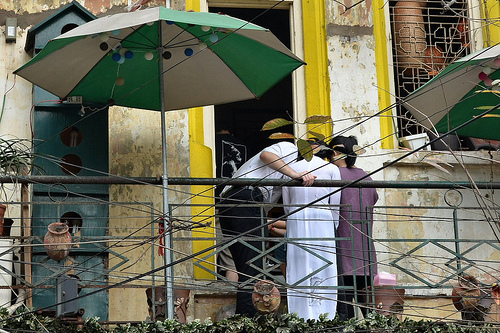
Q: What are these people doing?
A: Huddling.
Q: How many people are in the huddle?
A: Four.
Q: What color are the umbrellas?
A: Green and white.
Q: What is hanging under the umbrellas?
A: Light bulbs.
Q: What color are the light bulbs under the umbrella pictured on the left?
A: Blue and white.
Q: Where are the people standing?
A: A doorway.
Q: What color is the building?
A: White and yellow.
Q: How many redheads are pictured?
A: None.